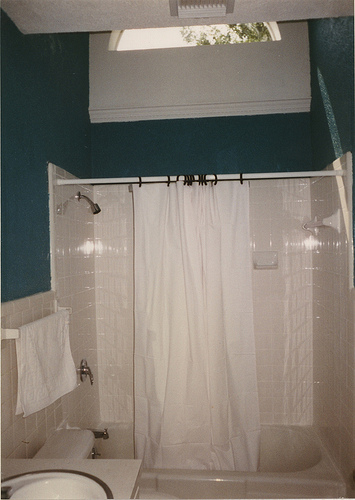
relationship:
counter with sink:
[3, 448, 151, 499] [0, 458, 120, 498]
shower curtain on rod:
[133, 181, 263, 474] [53, 168, 347, 186]